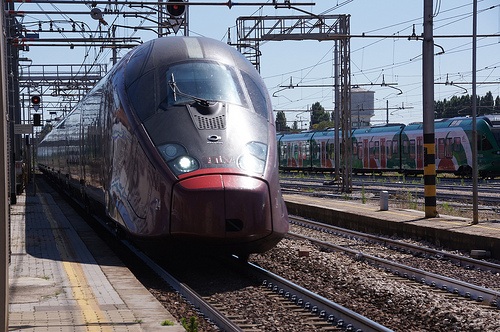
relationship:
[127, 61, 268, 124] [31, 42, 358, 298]
windshield in train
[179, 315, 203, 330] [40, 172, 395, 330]
weeds near tracks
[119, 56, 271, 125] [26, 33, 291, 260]
windshield on front of train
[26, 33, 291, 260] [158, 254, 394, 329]
train by track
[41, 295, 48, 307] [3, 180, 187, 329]
brick on sidewalk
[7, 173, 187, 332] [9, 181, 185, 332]
brick on platform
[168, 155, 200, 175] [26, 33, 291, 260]
headlight on train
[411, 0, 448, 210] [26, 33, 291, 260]
pole to right of train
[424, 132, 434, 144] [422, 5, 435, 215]
stripe to right of pole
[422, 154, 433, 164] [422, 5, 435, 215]
stripe to right of pole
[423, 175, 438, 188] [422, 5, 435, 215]
stripe to right of pole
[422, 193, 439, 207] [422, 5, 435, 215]
stripe to right of pole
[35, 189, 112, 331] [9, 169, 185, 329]
line on platform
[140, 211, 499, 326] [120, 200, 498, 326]
pebbles on tracks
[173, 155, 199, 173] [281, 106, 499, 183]
headlight on train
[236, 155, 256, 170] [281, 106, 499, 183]
headlight on train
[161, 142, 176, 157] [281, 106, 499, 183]
headlight on train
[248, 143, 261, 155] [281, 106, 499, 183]
headlight on train